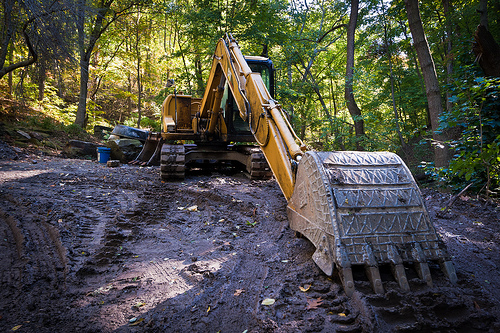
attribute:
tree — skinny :
[402, 3, 445, 149]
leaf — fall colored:
[459, 190, 469, 197]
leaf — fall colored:
[234, 287, 248, 297]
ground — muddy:
[6, 141, 495, 331]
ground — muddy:
[0, 110, 494, 328]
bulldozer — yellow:
[162, 36, 463, 288]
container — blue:
[95, 144, 109, 165]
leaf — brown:
[310, 296, 321, 311]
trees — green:
[4, 0, 495, 181]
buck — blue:
[95, 145, 110, 162]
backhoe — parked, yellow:
[157, 33, 456, 293]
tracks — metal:
[160, 140, 273, 184]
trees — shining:
[97, 24, 195, 105]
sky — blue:
[339, 8, 401, 29]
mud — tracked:
[48, 177, 229, 284]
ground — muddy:
[39, 178, 245, 289]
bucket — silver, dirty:
[295, 148, 440, 295]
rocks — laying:
[12, 96, 99, 158]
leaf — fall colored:
[276, 270, 354, 321]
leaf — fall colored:
[255, 289, 301, 317]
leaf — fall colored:
[205, 219, 250, 251]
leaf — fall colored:
[205, 291, 252, 319]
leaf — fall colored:
[172, 190, 221, 222]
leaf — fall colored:
[219, 276, 259, 308]